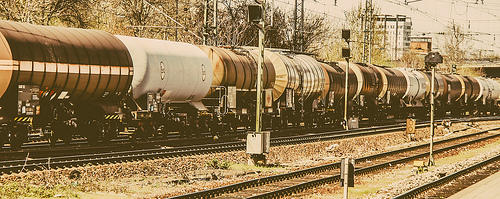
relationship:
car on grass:
[0, 20, 500, 156] [0, 121, 479, 199]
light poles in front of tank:
[246, 5, 270, 166] [128, 50, 225, 122]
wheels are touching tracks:
[8, 107, 281, 154] [0, 105, 500, 199]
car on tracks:
[0, 20, 500, 156] [231, 104, 424, 195]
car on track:
[396, 65, 434, 120] [0, 112, 498, 174]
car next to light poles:
[0, 20, 500, 156] [246, 5, 270, 166]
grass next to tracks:
[35, 140, 441, 195] [0, 105, 500, 199]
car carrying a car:
[0, 20, 500, 156] [0, 20, 500, 156]